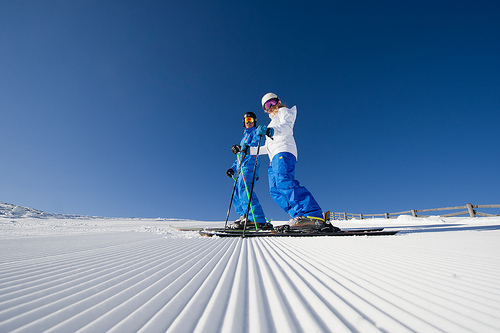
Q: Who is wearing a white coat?
A: The woman in front.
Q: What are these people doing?
A: Skiing.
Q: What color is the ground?
A: White.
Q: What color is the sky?
A: Blue.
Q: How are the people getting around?
A: Skiing.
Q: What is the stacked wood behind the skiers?
A: A fence.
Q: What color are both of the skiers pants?
A: Blue.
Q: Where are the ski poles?
A: In the skiers hands.